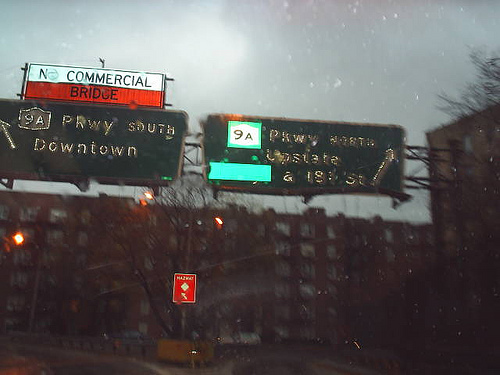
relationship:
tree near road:
[116, 177, 274, 336] [1, 343, 158, 373]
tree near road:
[116, 177, 274, 336] [236, 357, 360, 374]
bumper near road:
[156, 338, 216, 363] [1, 343, 158, 373]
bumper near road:
[156, 338, 216, 363] [236, 357, 360, 374]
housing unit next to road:
[2, 189, 437, 347] [1, 343, 158, 373]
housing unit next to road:
[426, 103, 498, 374] [236, 357, 360, 374]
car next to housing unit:
[105, 328, 153, 340] [2, 189, 437, 347]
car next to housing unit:
[216, 332, 260, 346] [2, 189, 437, 347]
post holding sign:
[446, 137, 474, 371] [201, 113, 406, 197]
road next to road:
[1, 343, 158, 373] [236, 357, 360, 374]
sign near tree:
[173, 272, 198, 303] [116, 177, 274, 336]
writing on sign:
[39, 66, 153, 100] [21, 62, 167, 110]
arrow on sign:
[180, 291, 190, 300] [173, 272, 198, 303]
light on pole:
[14, 234, 26, 244] [14, 233, 45, 330]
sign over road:
[0, 98, 188, 189] [1, 343, 158, 373]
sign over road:
[201, 113, 406, 197] [236, 357, 360, 374]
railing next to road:
[3, 326, 157, 358] [1, 343, 158, 373]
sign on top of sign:
[21, 62, 167, 110] [0, 98, 188, 189]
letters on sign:
[32, 114, 176, 158] [0, 98, 188, 189]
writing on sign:
[17, 106, 52, 129] [0, 98, 188, 189]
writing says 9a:
[17, 106, 52, 129] [24, 112, 46, 126]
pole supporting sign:
[180, 203, 188, 338] [173, 272, 198, 303]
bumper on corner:
[156, 338, 216, 363] [138, 335, 233, 374]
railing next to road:
[216, 342, 267, 363] [236, 357, 360, 374]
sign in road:
[173, 272, 198, 303] [1, 343, 158, 373]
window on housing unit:
[297, 243, 316, 259] [2, 189, 437, 347]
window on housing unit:
[300, 223, 314, 237] [2, 189, 437, 347]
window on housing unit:
[275, 281, 291, 297] [2, 189, 437, 347]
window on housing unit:
[49, 209, 68, 225] [2, 189, 437, 347]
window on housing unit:
[45, 229, 64, 243] [2, 189, 437, 347]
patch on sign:
[228, 120, 263, 149] [201, 113, 406, 197]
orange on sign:
[25, 80, 164, 106] [21, 62, 167, 110]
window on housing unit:
[18, 207, 40, 221] [2, 189, 437, 347]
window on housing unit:
[8, 297, 25, 311] [2, 189, 437, 347]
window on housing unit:
[11, 271, 26, 287] [2, 189, 437, 347]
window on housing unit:
[275, 221, 290, 237] [2, 189, 437, 347]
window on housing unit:
[327, 245, 340, 259] [2, 189, 437, 347]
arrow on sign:
[0, 120, 17, 149] [0, 98, 188, 189]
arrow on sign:
[371, 146, 397, 183] [201, 113, 406, 197]